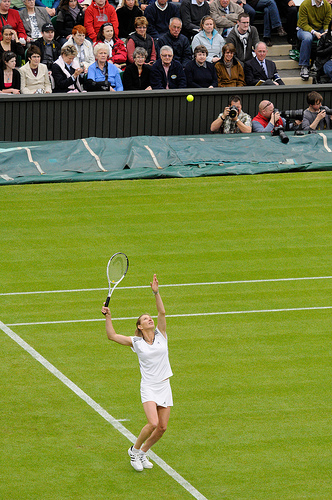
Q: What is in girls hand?
A: Tennis racket.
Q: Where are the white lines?
A: On grass.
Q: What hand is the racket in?
A: Right.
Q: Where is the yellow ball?
A: In air.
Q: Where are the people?
A: In stands.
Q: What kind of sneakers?
A: Adidas.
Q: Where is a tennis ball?
A: High in the air.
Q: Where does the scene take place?
A: At a tennis game.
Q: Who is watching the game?
A: Spectators.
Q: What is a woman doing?
A: Playing tennis.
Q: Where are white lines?
A: On the court.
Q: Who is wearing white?
A: Tennis player.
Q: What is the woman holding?
A: Tennis racket.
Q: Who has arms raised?
A: The woman.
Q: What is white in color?
A: Player's outfit.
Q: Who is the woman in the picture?
A: A tennis player.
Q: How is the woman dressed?
A: In white clothes.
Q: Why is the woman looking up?
A: To see the tennis ball in the air.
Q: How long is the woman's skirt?
A: Very short.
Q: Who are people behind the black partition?
A: Spectators.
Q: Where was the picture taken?
A: At the tennis court.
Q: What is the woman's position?
A: Standing with bent knees.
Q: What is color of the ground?
A: Green.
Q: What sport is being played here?
A: Tennis.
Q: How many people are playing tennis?
A: One.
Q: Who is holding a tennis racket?
A: The woman.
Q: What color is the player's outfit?
A: White.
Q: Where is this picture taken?
A: A tennis court.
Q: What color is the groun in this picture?
A: Green.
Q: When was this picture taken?
A: Daytime.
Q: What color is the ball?
A: Yellow.